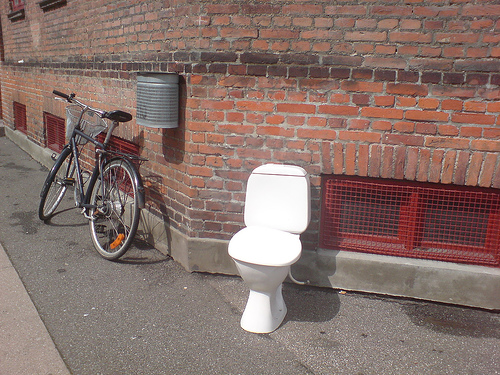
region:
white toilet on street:
[227, 163, 311, 338]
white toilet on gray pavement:
[224, 159, 314, 336]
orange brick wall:
[1, 0, 496, 278]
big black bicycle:
[34, 91, 144, 256]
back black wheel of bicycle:
[81, 151, 142, 265]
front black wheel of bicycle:
[32, 142, 73, 224]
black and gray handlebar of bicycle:
[48, 79, 129, 124]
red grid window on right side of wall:
[320, 167, 496, 264]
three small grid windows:
[7, 98, 143, 188]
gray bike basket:
[63, 101, 108, 143]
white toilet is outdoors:
[226, 152, 329, 354]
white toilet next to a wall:
[205, 132, 339, 346]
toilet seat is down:
[231, 163, 337, 353]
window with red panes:
[319, 168, 498, 265]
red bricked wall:
[229, 70, 436, 140]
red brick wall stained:
[221, 51, 420, 81]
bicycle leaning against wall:
[33, 90, 148, 257]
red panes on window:
[12, 99, 27, 133]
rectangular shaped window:
[319, 167, 499, 259]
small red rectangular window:
[323, 170, 498, 268]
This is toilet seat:
[205, 160, 307, 330]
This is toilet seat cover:
[207, 217, 317, 270]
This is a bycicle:
[40, 128, 166, 271]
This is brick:
[271, 97, 312, 118]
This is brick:
[316, 100, 356, 121]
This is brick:
[376, 76, 437, 109]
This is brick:
[225, 15, 265, 46]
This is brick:
[106, 25, 161, 53]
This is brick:
[215, 200, 244, 223]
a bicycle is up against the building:
[35, 79, 155, 267]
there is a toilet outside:
[230, 150, 315, 345]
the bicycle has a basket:
[63, 100, 105, 147]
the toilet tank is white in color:
[248, 160, 310, 232]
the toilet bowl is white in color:
[229, 226, 292, 294]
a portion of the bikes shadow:
[139, 183, 181, 269]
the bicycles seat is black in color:
[97, 102, 133, 133]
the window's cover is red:
[323, 166, 495, 266]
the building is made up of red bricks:
[259, 21, 444, 153]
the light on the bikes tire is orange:
[103, 229, 131, 254]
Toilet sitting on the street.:
[223, 160, 312, 336]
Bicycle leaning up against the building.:
[33, 89, 145, 266]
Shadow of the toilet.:
[283, 175, 344, 327]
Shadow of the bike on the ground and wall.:
[46, 122, 181, 274]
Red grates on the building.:
[3, 95, 494, 267]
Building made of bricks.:
[0, 0, 495, 305]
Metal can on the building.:
[130, 64, 185, 131]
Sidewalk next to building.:
[2, 133, 498, 373]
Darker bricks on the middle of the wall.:
[1, 44, 496, 99]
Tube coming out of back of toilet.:
[284, 265, 309, 287]